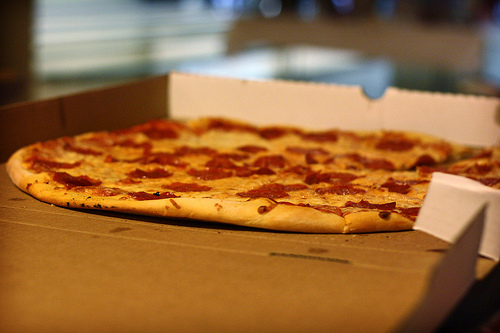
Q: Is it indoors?
A: Yes, it is indoors.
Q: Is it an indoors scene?
A: Yes, it is indoors.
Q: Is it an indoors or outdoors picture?
A: It is indoors.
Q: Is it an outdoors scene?
A: No, it is indoors.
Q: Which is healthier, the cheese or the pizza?
A: The cheese is healthier than the pizza.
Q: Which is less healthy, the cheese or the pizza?
A: The pizza is less healthy than the cheese.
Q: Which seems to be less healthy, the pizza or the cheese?
A: The pizza is less healthy than the cheese.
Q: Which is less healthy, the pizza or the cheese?
A: The pizza is less healthy than the cheese.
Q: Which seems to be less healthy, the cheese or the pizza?
A: The pizza is less healthy than the cheese.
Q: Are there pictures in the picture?
A: No, there are no pictures.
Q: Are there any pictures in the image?
A: No, there are no pictures.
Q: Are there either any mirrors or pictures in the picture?
A: No, there are no pictures or mirrors.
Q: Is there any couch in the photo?
A: No, there are no couches.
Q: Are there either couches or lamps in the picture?
A: No, there are no couches or lamps.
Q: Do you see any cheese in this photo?
A: Yes, there is cheese.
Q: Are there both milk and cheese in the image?
A: No, there is cheese but no milk.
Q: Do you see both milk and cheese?
A: No, there is cheese but no milk.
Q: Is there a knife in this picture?
A: No, there are no knives.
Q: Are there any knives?
A: No, there are no knives.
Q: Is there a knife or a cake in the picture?
A: No, there are no knives or cakes.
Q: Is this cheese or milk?
A: This is cheese.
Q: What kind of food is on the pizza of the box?
A: The food is cheese.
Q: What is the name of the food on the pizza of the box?
A: The food is cheese.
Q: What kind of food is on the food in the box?
A: The food is cheese.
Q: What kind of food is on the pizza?
A: The food is cheese.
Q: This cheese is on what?
A: The cheese is on the pizza.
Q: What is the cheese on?
A: The cheese is on the pizza.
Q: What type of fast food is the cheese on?
A: The cheese is on the pizza.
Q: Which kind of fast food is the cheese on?
A: The cheese is on the pizza.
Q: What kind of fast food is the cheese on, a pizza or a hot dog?
A: The cheese is on a pizza.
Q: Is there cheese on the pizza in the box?
A: Yes, there is cheese on the pizza.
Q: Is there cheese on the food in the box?
A: Yes, there is cheese on the pizza.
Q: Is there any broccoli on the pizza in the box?
A: No, there is cheese on the pizza.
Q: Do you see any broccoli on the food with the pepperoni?
A: No, there is cheese on the pizza.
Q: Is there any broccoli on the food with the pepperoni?
A: No, there is cheese on the pizza.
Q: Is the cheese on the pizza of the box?
A: Yes, the cheese is on the pizza.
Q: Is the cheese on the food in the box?
A: Yes, the cheese is on the pizza.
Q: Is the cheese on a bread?
A: No, the cheese is on the pizza.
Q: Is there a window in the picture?
A: Yes, there is a window.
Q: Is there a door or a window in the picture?
A: Yes, there is a window.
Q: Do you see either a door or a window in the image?
A: Yes, there is a window.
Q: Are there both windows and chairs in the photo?
A: No, there is a window but no chairs.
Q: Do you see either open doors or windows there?
A: Yes, there is an open window.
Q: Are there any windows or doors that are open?
A: Yes, the window is open.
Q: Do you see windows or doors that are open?
A: Yes, the window is open.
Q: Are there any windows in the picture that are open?
A: Yes, there is an open window.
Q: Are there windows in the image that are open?
A: Yes, there is a window that is open.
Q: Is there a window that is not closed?
A: Yes, there is a open window.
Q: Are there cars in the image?
A: No, there are no cars.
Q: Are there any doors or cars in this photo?
A: No, there are no cars or doors.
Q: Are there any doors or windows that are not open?
A: No, there is a window but it is open.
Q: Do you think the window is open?
A: Yes, the window is open.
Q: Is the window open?
A: Yes, the window is open.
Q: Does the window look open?
A: Yes, the window is open.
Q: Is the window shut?
A: No, the window is open.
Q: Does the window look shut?
A: No, the window is open.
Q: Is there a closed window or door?
A: No, there is a window but it is open.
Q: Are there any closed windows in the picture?
A: No, there is a window but it is open.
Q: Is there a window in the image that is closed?
A: No, there is a window but it is open.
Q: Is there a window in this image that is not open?
A: No, there is a window but it is open.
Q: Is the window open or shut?
A: The window is open.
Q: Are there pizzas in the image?
A: Yes, there is a pizza.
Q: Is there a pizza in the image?
A: Yes, there is a pizza.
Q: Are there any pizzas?
A: Yes, there is a pizza.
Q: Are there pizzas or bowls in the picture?
A: Yes, there is a pizza.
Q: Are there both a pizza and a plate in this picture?
A: No, there is a pizza but no plates.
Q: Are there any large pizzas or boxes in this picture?
A: Yes, there is a large pizza.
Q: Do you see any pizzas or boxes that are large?
A: Yes, the pizza is large.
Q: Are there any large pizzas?
A: Yes, there is a large pizza.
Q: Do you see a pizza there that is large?
A: Yes, there is a pizza that is large.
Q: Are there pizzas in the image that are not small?
A: Yes, there is a large pizza.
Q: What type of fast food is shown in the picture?
A: The fast food is a pizza.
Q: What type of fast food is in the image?
A: The fast food is a pizza.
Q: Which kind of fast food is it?
A: The food is a pizza.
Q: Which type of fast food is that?
A: This is a pizza.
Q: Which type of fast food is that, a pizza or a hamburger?
A: This is a pizza.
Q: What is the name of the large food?
A: The food is a pizza.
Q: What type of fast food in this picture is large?
A: The fast food is a pizza.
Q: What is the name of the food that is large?
A: The food is a pizza.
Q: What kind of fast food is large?
A: The fast food is a pizza.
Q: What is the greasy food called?
A: The food is a pizza.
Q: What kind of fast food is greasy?
A: The fast food is a pizza.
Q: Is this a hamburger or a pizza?
A: This is a pizza.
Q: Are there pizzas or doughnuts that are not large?
A: No, there is a pizza but it is large.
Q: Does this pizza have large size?
A: Yes, the pizza is large.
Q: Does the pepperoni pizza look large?
A: Yes, the pizza is large.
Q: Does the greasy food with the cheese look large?
A: Yes, the pizza is large.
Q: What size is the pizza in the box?
A: The pizza is large.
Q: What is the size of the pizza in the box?
A: The pizza is large.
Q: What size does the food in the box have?
A: The pizza has large size.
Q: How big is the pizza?
A: The pizza is large.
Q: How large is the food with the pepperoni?
A: The pizza is large.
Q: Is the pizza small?
A: No, the pizza is large.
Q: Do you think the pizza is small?
A: No, the pizza is large.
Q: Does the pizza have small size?
A: No, the pizza is large.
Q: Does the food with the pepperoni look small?
A: No, the pizza is large.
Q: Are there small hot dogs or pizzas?
A: No, there is a pizza but it is large.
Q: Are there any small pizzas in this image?
A: No, there is a pizza but it is large.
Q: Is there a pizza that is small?
A: No, there is a pizza but it is large.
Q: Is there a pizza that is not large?
A: No, there is a pizza but it is large.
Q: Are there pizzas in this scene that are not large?
A: No, there is a pizza but it is large.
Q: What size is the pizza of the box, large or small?
A: The pizza is large.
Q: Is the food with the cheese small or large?
A: The pizza is large.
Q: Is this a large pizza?
A: Yes, this is a large pizza.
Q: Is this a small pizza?
A: No, this is a large pizza.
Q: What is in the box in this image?
A: The pizza is in the box.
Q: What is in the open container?
A: The pizza is in the box.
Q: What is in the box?
A: The pizza is in the box.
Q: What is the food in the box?
A: The food is a pizza.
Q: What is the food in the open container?
A: The food is a pizza.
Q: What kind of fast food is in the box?
A: The food is a pizza.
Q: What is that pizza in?
A: The pizza is in the box.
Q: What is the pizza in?
A: The pizza is in the box.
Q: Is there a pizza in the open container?
A: Yes, there is a pizza in the box.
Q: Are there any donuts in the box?
A: No, there is a pizza in the box.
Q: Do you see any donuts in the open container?
A: No, there is a pizza in the box.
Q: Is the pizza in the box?
A: Yes, the pizza is in the box.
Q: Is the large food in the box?
A: Yes, the pizza is in the box.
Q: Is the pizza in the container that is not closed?
A: Yes, the pizza is in the box.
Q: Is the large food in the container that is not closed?
A: Yes, the pizza is in the box.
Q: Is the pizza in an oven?
A: No, the pizza is in the box.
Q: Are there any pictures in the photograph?
A: No, there are no pictures.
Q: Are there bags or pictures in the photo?
A: No, there are no pictures or bags.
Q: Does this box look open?
A: Yes, the box is open.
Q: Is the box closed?
A: No, the box is open.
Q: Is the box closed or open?
A: The box is open.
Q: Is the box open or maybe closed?
A: The box is open.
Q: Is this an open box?
A: Yes, this is an open box.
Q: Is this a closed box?
A: No, this is an open box.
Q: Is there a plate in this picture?
A: No, there are no plates.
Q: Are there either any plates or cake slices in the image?
A: No, there are no plates or cake slices.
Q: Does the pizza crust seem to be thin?
A: Yes, the crust is thin.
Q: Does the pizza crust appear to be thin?
A: Yes, the crust is thin.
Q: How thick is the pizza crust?
A: The crust is thin.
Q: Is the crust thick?
A: No, the crust is thin.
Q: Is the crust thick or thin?
A: The crust is thin.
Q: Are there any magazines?
A: No, there are no magazines.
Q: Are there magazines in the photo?
A: No, there are no magazines.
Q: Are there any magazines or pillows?
A: No, there are no magazines or pillows.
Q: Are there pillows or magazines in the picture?
A: No, there are no magazines or pillows.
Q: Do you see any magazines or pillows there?
A: No, there are no magazines or pillows.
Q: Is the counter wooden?
A: Yes, the counter is wooden.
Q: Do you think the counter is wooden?
A: Yes, the counter is wooden.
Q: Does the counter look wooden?
A: Yes, the counter is wooden.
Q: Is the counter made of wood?
A: Yes, the counter is made of wood.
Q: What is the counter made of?
A: The counter is made of wood.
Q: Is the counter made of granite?
A: No, the counter is made of wood.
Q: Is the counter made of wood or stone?
A: The counter is made of wood.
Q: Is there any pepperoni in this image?
A: Yes, there is pepperoni.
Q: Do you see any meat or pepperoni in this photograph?
A: Yes, there is pepperoni.